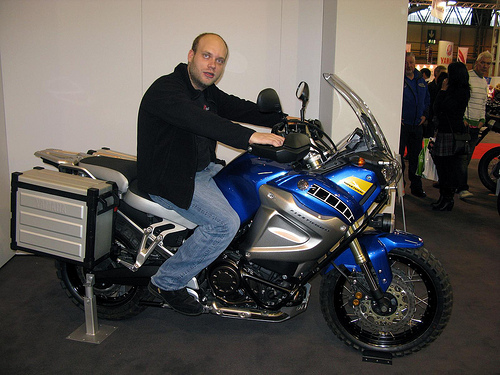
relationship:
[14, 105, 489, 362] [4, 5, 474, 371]
motorcycle in exhibition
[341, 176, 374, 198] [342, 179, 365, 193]
yellow box with black writing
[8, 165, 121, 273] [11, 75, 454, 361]
box for motorcycle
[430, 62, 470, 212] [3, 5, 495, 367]
guest at show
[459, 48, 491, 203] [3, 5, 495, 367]
guest at show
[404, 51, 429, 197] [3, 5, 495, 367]
guest at show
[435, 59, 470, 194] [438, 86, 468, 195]
woman wearing clothing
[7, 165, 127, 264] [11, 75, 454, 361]
box on motorcycle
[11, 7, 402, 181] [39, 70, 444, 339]
wall behind motorcycle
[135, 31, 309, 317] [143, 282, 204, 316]
man wearing shoe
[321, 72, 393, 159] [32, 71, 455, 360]
windshield on motorcycle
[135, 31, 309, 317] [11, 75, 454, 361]
man on motorcycle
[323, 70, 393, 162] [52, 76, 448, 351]
windshield on bike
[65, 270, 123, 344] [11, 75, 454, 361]
stand supporting motorcycle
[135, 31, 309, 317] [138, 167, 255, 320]
man wearing jeans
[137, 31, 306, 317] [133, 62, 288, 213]
man wearing jacket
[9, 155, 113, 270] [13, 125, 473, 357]
cases on bike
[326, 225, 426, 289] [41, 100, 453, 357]
fender on bike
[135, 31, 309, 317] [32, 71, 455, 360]
man on motorcycle